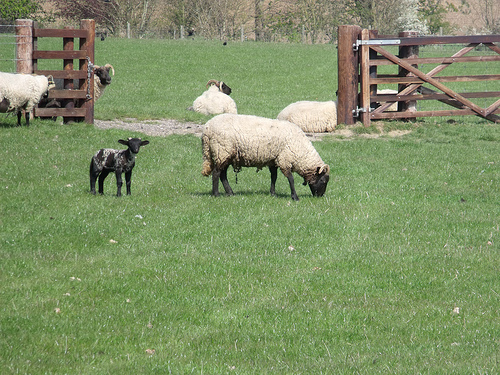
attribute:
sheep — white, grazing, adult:
[198, 111, 330, 203]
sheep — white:
[1, 70, 54, 126]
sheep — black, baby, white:
[87, 137, 150, 195]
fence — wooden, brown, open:
[336, 22, 499, 130]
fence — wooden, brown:
[17, 19, 96, 130]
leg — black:
[285, 171, 300, 205]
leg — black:
[266, 164, 278, 196]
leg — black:
[221, 172, 236, 198]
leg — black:
[210, 164, 225, 197]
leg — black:
[24, 108, 32, 126]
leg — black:
[17, 105, 24, 128]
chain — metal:
[83, 55, 89, 108]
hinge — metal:
[350, 106, 374, 118]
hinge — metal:
[351, 38, 402, 50]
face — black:
[308, 171, 329, 197]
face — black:
[219, 82, 235, 94]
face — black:
[95, 67, 111, 86]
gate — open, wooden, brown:
[360, 26, 499, 125]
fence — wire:
[0, 22, 33, 74]